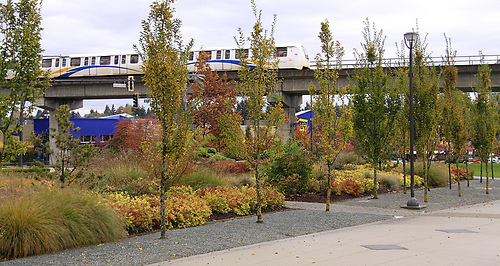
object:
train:
[0, 43, 313, 79]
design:
[45, 65, 144, 78]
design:
[182, 60, 257, 70]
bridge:
[1, 55, 500, 97]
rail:
[310, 54, 499, 72]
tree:
[134, 0, 195, 239]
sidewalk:
[1, 177, 499, 266]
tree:
[217, 2, 285, 224]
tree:
[305, 18, 355, 213]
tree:
[353, 17, 403, 200]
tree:
[403, 18, 443, 201]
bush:
[99, 190, 157, 235]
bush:
[145, 187, 213, 228]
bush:
[195, 183, 253, 219]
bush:
[243, 181, 287, 212]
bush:
[1, 190, 131, 258]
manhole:
[360, 244, 409, 250]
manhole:
[435, 229, 479, 234]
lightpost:
[401, 31, 425, 209]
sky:
[1, 0, 500, 69]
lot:
[387, 158, 499, 165]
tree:
[438, 32, 478, 197]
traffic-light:
[127, 75, 136, 92]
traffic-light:
[133, 92, 141, 109]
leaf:
[105, 260, 111, 263]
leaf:
[81, 252, 86, 255]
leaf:
[96, 243, 105, 246]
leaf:
[138, 247, 143, 250]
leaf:
[153, 243, 158, 246]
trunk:
[160, 125, 166, 239]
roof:
[99, 112, 146, 119]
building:
[33, 118, 141, 151]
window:
[100, 56, 110, 65]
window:
[70, 58, 80, 66]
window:
[131, 54, 139, 63]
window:
[42, 59, 52, 68]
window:
[275, 47, 287, 57]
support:
[33, 94, 84, 172]